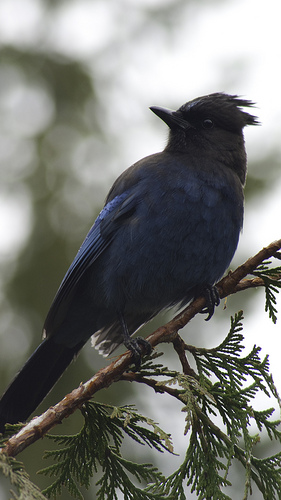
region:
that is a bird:
[6, 94, 242, 419]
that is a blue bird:
[0, 92, 245, 407]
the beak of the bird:
[151, 91, 180, 133]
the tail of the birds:
[0, 309, 65, 429]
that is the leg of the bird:
[112, 309, 152, 357]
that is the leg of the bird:
[208, 281, 226, 321]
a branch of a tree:
[21, 399, 89, 476]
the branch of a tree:
[150, 308, 229, 391]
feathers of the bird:
[148, 194, 191, 222]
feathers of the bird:
[116, 253, 158, 277]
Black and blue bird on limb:
[34, 92, 256, 480]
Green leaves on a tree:
[20, 406, 136, 499]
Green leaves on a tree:
[119, 367, 238, 439]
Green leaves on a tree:
[162, 426, 235, 498]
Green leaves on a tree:
[224, 427, 280, 484]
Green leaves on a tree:
[170, 339, 279, 419]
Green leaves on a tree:
[242, 245, 280, 292]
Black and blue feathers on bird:
[35, 237, 104, 298]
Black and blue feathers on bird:
[102, 259, 146, 311]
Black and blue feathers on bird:
[126, 215, 154, 256]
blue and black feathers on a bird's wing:
[37, 185, 135, 321]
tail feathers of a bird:
[0, 335, 93, 420]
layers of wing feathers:
[62, 242, 108, 288]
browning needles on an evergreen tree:
[111, 403, 172, 447]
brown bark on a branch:
[46, 376, 98, 426]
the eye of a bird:
[203, 117, 217, 130]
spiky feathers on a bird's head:
[208, 86, 258, 124]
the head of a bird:
[154, 76, 257, 164]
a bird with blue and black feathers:
[73, 112, 260, 301]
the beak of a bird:
[148, 104, 192, 132]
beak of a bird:
[148, 105, 188, 131]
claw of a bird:
[112, 305, 147, 368]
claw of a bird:
[193, 281, 219, 322]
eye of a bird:
[200, 116, 212, 130]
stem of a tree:
[0, 237, 280, 497]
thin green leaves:
[40, 271, 280, 498]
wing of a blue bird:
[37, 187, 128, 335]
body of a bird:
[107, 158, 241, 304]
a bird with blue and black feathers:
[10, 65, 251, 400]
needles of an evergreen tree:
[194, 340, 266, 393]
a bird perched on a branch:
[41, 74, 264, 365]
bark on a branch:
[58, 391, 82, 414]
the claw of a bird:
[123, 329, 153, 365]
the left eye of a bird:
[202, 114, 215, 130]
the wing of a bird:
[38, 178, 143, 322]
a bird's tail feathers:
[1, 322, 77, 427]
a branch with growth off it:
[20, 239, 272, 481]